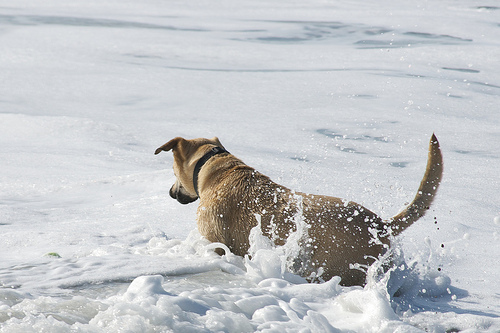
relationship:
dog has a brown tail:
[154, 132, 444, 290] [382, 131, 445, 236]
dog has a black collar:
[154, 132, 444, 290] [193, 147, 230, 197]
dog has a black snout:
[154, 132, 444, 290] [170, 178, 199, 204]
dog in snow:
[154, 132, 444, 290] [0, 0, 500, 332]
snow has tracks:
[0, 0, 500, 332] [233, 0, 499, 169]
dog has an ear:
[154, 132, 444, 290] [154, 137, 182, 156]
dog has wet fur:
[154, 132, 444, 290] [200, 170, 390, 294]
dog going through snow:
[154, 132, 444, 290] [0, 0, 500, 332]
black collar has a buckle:
[193, 147, 230, 197] [212, 146, 222, 153]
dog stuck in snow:
[154, 132, 444, 290] [0, 0, 500, 332]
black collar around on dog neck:
[193, 147, 230, 197] [188, 143, 235, 196]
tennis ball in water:
[45, 251, 62, 257] [0, 253, 430, 332]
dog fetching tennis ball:
[154, 132, 444, 290] [45, 251, 62, 257]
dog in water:
[154, 132, 444, 290] [0, 253, 430, 332]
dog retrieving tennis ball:
[154, 132, 444, 290] [45, 251, 62, 257]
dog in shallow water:
[154, 132, 444, 290] [0, 253, 430, 332]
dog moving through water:
[154, 132, 444, 290] [0, 253, 430, 332]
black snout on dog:
[170, 178, 199, 204] [154, 132, 444, 290]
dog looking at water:
[154, 132, 444, 290] [0, 253, 430, 332]